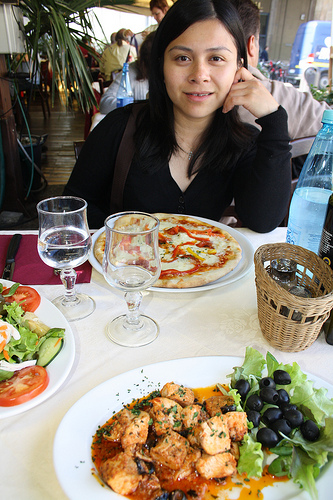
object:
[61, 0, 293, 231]
woman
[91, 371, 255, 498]
chicken dish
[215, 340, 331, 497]
salad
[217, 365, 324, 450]
black olives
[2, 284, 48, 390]
salad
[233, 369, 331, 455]
olives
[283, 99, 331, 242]
bottle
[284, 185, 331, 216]
water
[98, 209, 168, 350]
wine glass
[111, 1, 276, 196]
hair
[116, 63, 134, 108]
bottle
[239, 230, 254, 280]
white plate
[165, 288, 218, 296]
white plate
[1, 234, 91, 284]
red napkin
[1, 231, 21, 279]
knife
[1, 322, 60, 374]
salad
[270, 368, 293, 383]
olives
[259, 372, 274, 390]
olives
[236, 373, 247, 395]
olives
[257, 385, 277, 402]
olives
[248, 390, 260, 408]
olives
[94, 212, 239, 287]
pizza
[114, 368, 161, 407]
green herb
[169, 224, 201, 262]
peppers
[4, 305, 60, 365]
birdgreen lettuce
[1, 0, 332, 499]
restaurant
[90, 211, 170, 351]
glass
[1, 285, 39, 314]
tomato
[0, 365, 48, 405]
tomato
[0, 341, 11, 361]
carrot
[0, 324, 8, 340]
carrot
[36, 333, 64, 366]
cucumber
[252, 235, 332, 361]
basket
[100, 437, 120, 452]
sauce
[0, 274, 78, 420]
plate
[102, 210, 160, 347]
empty glass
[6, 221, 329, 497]
tablecloth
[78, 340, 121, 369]
line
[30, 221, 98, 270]
water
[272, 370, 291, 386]
olive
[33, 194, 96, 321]
glass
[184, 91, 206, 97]
tooth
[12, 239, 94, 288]
napkin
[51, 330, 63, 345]
carrot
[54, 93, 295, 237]
black shirt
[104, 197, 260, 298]
dish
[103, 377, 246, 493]
chicken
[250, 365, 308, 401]
lettuce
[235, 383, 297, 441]
olives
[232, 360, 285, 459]
lettuce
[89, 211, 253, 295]
plate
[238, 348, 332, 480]
herb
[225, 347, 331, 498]
herbs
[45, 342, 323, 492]
plate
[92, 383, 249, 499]
sauce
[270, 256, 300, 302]
salt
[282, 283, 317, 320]
pepper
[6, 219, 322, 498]
table